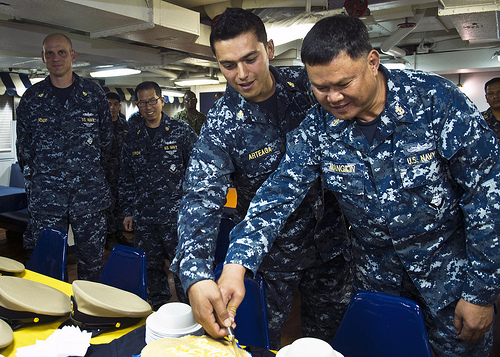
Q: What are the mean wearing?
A: A uniform.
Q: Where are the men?
A: By a table.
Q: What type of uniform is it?
A: A military one.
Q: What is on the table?
A: Hats.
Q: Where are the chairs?
A: By the table.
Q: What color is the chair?
A: Blue.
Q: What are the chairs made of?
A: Plastic.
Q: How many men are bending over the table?
A: Two.